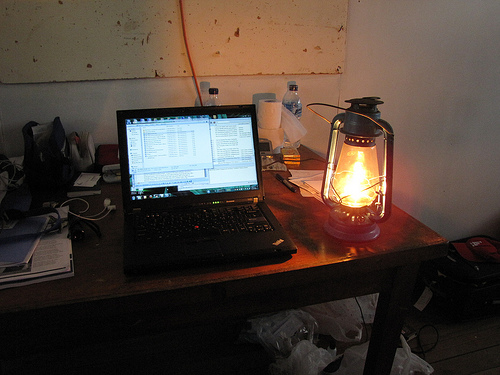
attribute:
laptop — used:
[112, 102, 299, 274]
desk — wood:
[2, 122, 448, 374]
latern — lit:
[306, 88, 401, 245]